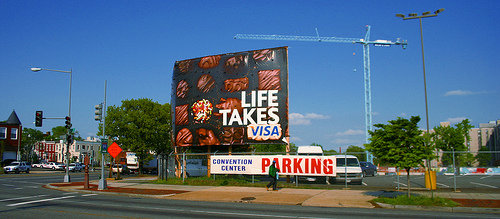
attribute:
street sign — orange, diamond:
[106, 140, 125, 161]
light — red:
[334, 10, 434, 180]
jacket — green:
[258, 160, 285, 180]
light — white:
[333, 10, 437, 210]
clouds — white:
[285, 94, 390, 146]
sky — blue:
[29, 19, 128, 65]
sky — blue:
[54, 18, 150, 77]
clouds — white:
[289, 98, 378, 146]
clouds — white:
[291, 110, 360, 140]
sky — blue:
[38, 15, 131, 61]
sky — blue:
[52, 20, 177, 80]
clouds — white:
[294, 100, 367, 138]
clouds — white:
[300, 110, 369, 151]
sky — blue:
[74, 12, 166, 53]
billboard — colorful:
[164, 48, 297, 150]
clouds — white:
[293, 108, 373, 154]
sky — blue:
[68, 23, 161, 52]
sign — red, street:
[104, 140, 128, 155]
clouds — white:
[294, 99, 374, 132]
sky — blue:
[93, 15, 160, 39]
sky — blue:
[95, 20, 146, 34]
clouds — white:
[287, 94, 357, 135]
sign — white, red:
[208, 142, 336, 179]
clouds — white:
[287, 101, 364, 151]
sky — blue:
[62, 18, 163, 46]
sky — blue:
[98, 9, 176, 44]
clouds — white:
[289, 105, 364, 143]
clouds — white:
[304, 105, 336, 129]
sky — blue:
[84, 7, 162, 44]